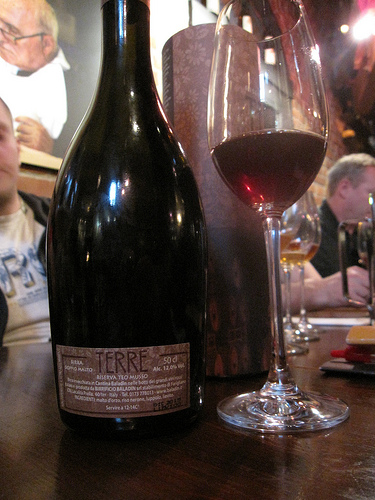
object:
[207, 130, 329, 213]
wine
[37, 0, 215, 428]
bottle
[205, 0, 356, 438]
glass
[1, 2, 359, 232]
wall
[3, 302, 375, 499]
table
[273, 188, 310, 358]
glasses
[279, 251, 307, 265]
wine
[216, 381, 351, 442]
base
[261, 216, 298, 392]
stem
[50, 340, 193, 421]
label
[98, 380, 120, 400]
words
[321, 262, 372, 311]
hand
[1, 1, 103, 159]
picture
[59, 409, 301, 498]
shadow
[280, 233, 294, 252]
wine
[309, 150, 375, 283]
man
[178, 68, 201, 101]
print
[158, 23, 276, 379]
wrap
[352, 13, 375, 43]
lights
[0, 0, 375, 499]
bar